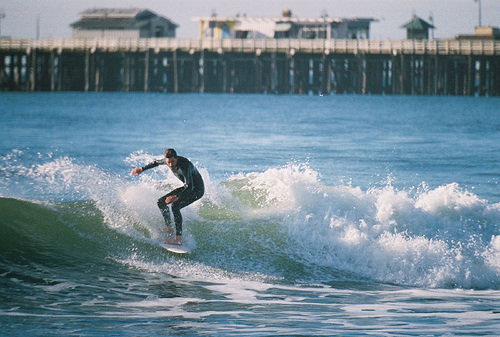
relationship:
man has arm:
[128, 147, 205, 245] [175, 168, 195, 202]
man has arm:
[128, 147, 205, 245] [138, 153, 168, 173]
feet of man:
[161, 237, 182, 245] [128, 147, 205, 245]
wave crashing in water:
[0, 146, 500, 337] [0, 86, 498, 335]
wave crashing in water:
[212, 163, 494, 235] [0, 86, 498, 335]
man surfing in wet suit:
[128, 147, 205, 245] [142, 157, 206, 236]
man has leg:
[128, 147, 205, 245] [170, 186, 206, 239]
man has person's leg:
[128, 147, 205, 245] [154, 186, 185, 230]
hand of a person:
[110, 161, 169, 186] [122, 120, 247, 262]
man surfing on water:
[124, 146, 206, 241] [0, 86, 498, 335]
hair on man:
[163, 147, 177, 160] [128, 147, 205, 245]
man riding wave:
[128, 147, 205, 245] [12, 190, 137, 272]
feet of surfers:
[153, 221, 185, 243] [125, 143, 207, 248]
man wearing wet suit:
[128, 147, 205, 245] [142, 157, 206, 236]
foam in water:
[208, 282, 257, 296] [0, 86, 498, 335]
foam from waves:
[208, 282, 257, 296] [1, 160, 496, 302]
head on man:
[157, 146, 180, 170] [128, 147, 205, 245]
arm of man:
[134, 154, 174, 179] [128, 147, 205, 245]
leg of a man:
[154, 184, 202, 236] [128, 147, 205, 245]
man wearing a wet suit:
[128, 147, 205, 245] [139, 155, 204, 237]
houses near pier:
[103, 54, 183, 100] [414, 32, 453, 58]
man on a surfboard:
[128, 147, 205, 245] [138, 206, 193, 256]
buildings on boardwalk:
[66, 0, 497, 46] [0, 31, 476, 95]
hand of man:
[163, 192, 177, 205] [128, 147, 205, 245]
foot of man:
[158, 227, 174, 234] [128, 147, 205, 245]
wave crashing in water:
[0, 146, 500, 337] [13, 105, 433, 334]